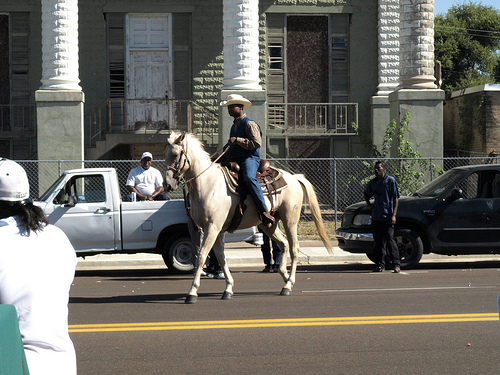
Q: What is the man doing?
A: Riding horse.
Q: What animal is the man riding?
A: Horse.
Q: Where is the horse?
A: On street.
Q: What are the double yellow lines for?
A: Traffic control.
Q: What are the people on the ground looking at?
A: Man on horse.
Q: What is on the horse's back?
A: Bridle.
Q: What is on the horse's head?
A: Harness.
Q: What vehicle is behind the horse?
A: White truck.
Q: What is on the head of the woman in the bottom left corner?
A: Hat.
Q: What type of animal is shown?
A: Horse.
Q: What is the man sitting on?
A: Saddle.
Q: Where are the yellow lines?
A: Street.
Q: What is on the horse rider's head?
A: Hat.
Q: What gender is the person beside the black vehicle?
A: Male.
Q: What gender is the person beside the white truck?
A: Male.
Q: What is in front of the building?
A: Fence.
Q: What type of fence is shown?
A: Chain link fence.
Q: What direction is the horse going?
A: Left.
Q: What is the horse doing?
A: Walking.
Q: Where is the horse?
A: Under the man.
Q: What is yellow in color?
A: The line on the road.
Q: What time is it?
A: Afternoon.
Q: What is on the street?
A: A car.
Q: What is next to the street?
A: A building.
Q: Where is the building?
A: Next to the street.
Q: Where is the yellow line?
A: Middle of the road.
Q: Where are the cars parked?
A: Next to curb.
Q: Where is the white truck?
A: On left.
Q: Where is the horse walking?
A: Street.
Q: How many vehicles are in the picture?
A: 2.